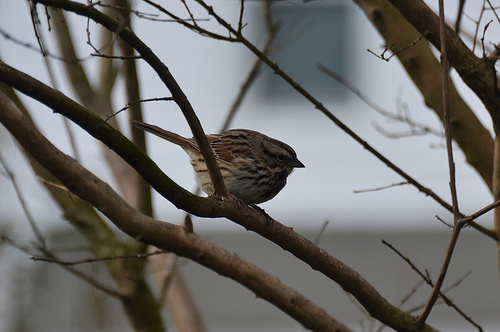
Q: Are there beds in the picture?
A: No, there are no beds.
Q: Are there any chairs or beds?
A: No, there are no beds or chairs.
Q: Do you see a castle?
A: No, there are no castles.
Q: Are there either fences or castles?
A: No, there are no castles or fences.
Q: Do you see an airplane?
A: No, there are no airplanes.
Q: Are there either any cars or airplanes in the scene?
A: No, there are no airplanes or cars.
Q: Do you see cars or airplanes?
A: No, there are no airplanes or cars.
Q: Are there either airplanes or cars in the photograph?
A: No, there are no airplanes or cars.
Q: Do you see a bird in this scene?
A: Yes, there is a bird.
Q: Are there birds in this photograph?
A: Yes, there is a bird.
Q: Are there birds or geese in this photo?
A: Yes, there is a bird.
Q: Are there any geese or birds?
A: Yes, there is a bird.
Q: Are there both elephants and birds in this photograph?
A: No, there is a bird but no elephants.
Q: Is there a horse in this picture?
A: No, there are no horses.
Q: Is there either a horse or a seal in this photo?
A: No, there are no horses or seals.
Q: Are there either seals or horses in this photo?
A: No, there are no horses or seals.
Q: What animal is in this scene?
A: The animal is a bird.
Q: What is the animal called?
A: The animal is a bird.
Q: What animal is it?
A: The animal is a bird.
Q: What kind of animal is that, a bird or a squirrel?
A: This is a bird.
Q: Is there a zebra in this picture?
A: No, there are no zebras.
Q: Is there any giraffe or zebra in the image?
A: No, there are no zebras or giraffes.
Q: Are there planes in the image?
A: No, there are no planes.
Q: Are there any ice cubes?
A: No, there are no ice cubes.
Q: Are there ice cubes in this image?
A: No, there are no ice cubes.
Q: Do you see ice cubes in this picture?
A: No, there are no ice cubes.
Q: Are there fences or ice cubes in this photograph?
A: No, there are no ice cubes or fences.